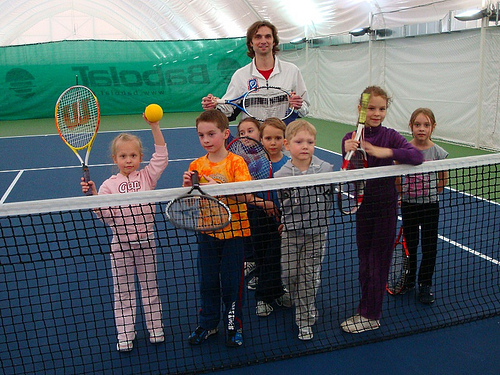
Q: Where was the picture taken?
A: Tennis court.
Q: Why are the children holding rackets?
A: To play tennis.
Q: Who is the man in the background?
A: The coach.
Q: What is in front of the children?
A: A net.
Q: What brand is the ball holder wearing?
A: Gap.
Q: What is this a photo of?
A: A court.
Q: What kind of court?
A: A tennis court.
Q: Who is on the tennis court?
A: Tennis players.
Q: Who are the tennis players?
A: Children.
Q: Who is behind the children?
A: The coach.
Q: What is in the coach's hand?
A: A tennis racket.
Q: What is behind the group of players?
A: A poster.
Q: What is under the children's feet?
A: The court.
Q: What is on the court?
A: White lines.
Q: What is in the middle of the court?
A: A tennis net.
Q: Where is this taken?
A: A tennis court.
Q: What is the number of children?
A: Seven.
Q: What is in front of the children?
A: A tennis net.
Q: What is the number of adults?
A: One.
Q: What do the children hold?
A: Tennis rackets.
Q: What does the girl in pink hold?
A: A yellow ball.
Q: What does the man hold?
A: A tennis racket.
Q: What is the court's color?
A: Blue.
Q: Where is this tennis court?
A: This is an indoor court.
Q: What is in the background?
A: A green banner.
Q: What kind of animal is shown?
A: None.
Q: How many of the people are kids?
A: Seven.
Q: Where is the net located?
A: In front of the people.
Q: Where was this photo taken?
A: A tennis court.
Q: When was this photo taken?
A: Daytime.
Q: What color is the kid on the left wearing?
A: Pink.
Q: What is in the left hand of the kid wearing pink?
A: A tennis ball.